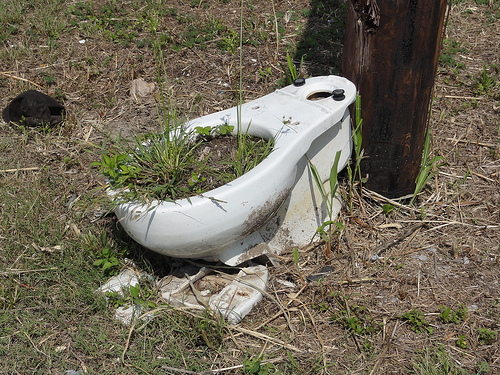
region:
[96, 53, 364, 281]
toilet bowl in the dirt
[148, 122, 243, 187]
weeds growing in a toilet bowl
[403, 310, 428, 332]
patch of grass on ground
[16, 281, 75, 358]
dead grass on ground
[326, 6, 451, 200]
wooden pole in ground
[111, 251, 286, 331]
trash on ground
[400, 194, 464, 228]
hay on the ground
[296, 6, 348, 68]
shadow casted on the ground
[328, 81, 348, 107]
screw on a toilet bowl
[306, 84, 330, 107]
hole for a pipe on toilet bowl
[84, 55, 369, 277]
broken white toilet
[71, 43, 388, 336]
toilet on ground with grass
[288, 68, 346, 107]
two black toilet knobs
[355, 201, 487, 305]
dried brown grass and dirt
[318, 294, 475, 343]
tufts of green grass in dirt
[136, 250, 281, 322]
cracked white pieces of toilet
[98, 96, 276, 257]
grass and dirt inside toilet bowl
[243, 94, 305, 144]
two holes in toilet bowl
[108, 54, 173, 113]
white rock in dirt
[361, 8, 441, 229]
dark brown telephone pole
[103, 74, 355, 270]
a broken white toilet bowl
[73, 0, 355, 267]
a broken toilet on the ground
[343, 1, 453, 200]
the lower part of a utility pole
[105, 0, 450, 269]
a white toilet bowl in front of a brown utility pole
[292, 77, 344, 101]
two black screws on the towel bowl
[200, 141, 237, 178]
dirt inside the white broken toilet bowl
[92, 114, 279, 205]
grass and weeds inside the toilet bowl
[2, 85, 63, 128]
black fabric item on the ground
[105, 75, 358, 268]
a broken toilet on abandon property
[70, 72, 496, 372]
a toilet bowl in a field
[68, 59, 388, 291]
a broken toilet seat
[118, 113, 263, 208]
weeds growing out of a toilet bowl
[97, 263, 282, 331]
broken pieces of the toilet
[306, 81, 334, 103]
small hole in back of toilet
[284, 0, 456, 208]
brown wooden pole behind toilet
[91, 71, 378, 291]
a white toilet bowl used as a planter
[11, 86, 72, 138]
a black rock on the ground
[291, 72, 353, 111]
two black knobs on back of toilet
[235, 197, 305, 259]
brown dirt on side of toilet bowl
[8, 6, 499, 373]
brown grown with grassy patches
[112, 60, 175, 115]
rock laying in field of grass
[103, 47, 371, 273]
broken toilet laying outside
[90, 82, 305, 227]
grass growing out of broken toilet bowl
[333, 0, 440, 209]
brown wooden pole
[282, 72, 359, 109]
black bolts on back of broken toilet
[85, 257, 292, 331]
broken toilet seat laying on ground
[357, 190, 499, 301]
ground covered in brown grass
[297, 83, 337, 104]
hole in back of toilet bowl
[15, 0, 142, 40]
grass growing on ground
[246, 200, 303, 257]
dirt on side of broken toilet bowl